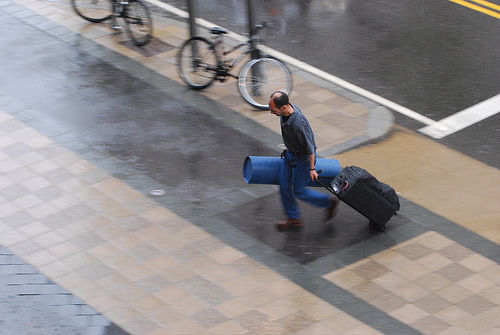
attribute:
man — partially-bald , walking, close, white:
[254, 89, 341, 237]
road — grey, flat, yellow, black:
[151, 4, 497, 139]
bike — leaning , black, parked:
[168, 20, 292, 111]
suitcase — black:
[318, 166, 404, 229]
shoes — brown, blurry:
[265, 194, 344, 232]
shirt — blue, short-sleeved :
[275, 104, 318, 172]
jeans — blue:
[275, 152, 337, 236]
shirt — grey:
[270, 110, 319, 166]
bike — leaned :
[176, 11, 296, 111]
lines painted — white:
[145, 0, 498, 144]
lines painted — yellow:
[434, 0, 498, 21]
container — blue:
[239, 152, 350, 185]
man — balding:
[267, 90, 344, 233]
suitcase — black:
[333, 164, 403, 224]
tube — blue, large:
[239, 153, 340, 187]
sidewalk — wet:
[0, 0, 498, 331]